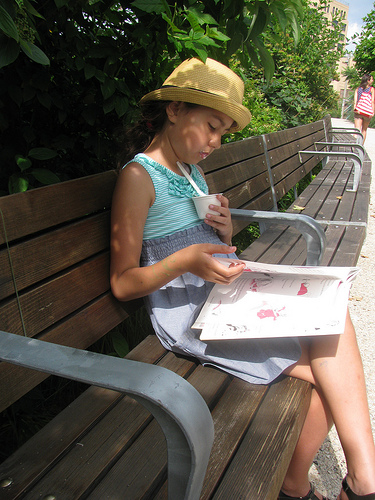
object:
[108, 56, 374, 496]
girl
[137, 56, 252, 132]
hat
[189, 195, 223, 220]
container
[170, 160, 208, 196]
spoon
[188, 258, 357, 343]
book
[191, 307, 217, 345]
lap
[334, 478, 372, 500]
sandals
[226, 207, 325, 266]
armrest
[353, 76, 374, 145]
woman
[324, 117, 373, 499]
sidewalk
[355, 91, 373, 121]
bag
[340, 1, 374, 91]
trees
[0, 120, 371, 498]
bench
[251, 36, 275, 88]
leaves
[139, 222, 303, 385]
skirt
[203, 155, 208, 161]
food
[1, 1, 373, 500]
park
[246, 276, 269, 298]
pictures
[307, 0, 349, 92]
building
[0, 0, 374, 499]
background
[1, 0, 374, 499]
photo